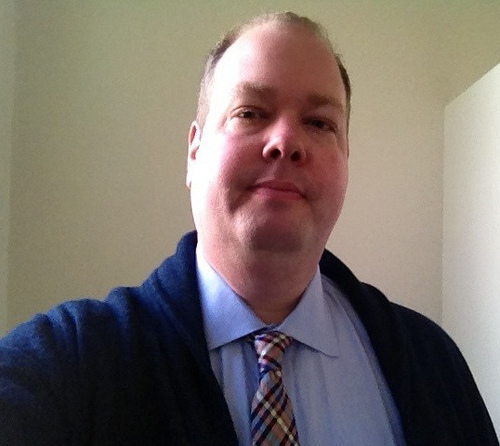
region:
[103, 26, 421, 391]
this person is male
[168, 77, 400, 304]
this person is middle aged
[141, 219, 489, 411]
his sweater is blue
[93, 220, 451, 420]
his shirt is blue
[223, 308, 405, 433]
his tie is plaid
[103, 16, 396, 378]
the man has thinning hair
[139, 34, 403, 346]
the man has dark eyes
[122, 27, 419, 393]
this man is overweight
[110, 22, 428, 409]
he is dressed business casual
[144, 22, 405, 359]
the man has a double chin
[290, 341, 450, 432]
the polo is blue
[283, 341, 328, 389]
the polo is blue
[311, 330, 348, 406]
the polo is blue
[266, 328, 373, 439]
the polo is blue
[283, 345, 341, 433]
the polo is blue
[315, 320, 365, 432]
the polo is blue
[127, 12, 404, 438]
Caucasian man posing for photo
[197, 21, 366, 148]
Man with receding hairline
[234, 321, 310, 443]
Blue, brown, peach and white plaid necktie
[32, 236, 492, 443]
Man wearing blue cardigan sweater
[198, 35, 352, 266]
Clean shaven man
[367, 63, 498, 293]
White painted wall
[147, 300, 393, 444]
Man's blue dress shirt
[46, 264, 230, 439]
Navy blue sweater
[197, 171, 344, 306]
Double chin on a heavy-set person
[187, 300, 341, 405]
Windsor knot on a necktie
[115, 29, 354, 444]
this is a man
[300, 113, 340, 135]
this is the eye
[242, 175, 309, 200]
the mouth is closed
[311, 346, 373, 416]
the shirt is blue in color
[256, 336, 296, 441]
this is the neck tie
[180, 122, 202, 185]
this is the ear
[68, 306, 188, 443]
this is a pullover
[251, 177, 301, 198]
the lips are red in color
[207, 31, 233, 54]
the hair is short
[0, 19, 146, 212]
the wall is white in color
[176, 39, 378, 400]
this is a man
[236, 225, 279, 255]
the man is light skinned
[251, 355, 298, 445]
this is a neck tie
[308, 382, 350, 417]
this is a shirt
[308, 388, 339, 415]
the shirt is blue in color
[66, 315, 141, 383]
this is a jacket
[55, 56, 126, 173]
this is a wall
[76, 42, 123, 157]
the wall is white in color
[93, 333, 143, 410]
the jacket is black in color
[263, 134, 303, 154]
this is the nose